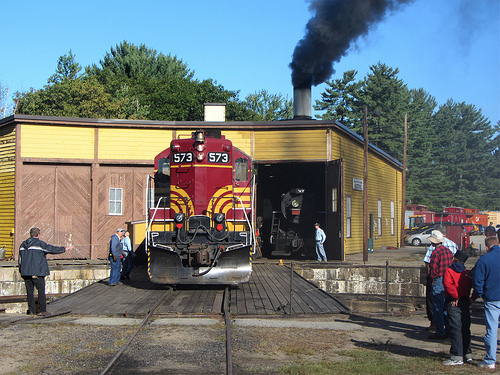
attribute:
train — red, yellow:
[114, 96, 277, 306]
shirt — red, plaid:
[424, 240, 458, 284]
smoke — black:
[290, 1, 408, 91]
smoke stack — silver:
[292, 80, 313, 119]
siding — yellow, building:
[282, 133, 422, 240]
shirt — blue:
[474, 243, 481, 282]